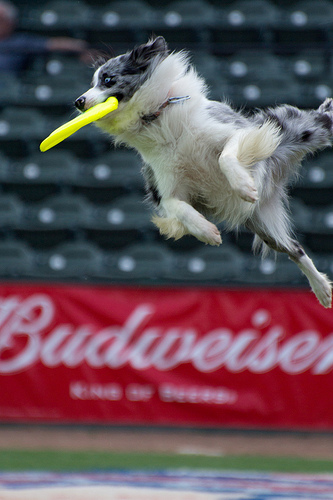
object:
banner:
[0, 282, 332, 430]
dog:
[71, 31, 333, 315]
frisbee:
[37, 95, 118, 152]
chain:
[167, 93, 192, 106]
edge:
[0, 419, 333, 498]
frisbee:
[37, 95, 120, 159]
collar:
[137, 83, 178, 128]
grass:
[0, 442, 333, 473]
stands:
[6, 249, 20, 278]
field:
[0, 421, 332, 500]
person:
[0, 0, 91, 76]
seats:
[35, 70, 91, 143]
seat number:
[37, 207, 56, 225]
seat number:
[188, 256, 206, 274]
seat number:
[294, 60, 310, 77]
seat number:
[45, 59, 61, 76]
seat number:
[258, 257, 277, 276]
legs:
[257, 212, 333, 312]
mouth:
[82, 89, 124, 123]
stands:
[292, 259, 333, 290]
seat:
[0, 121, 34, 185]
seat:
[0, 148, 78, 231]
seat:
[62, 149, 137, 232]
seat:
[73, 191, 150, 281]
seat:
[290, 52, 333, 189]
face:
[73, 32, 172, 140]